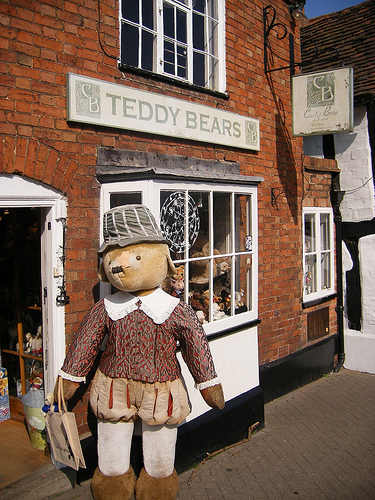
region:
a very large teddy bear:
[44, 191, 233, 492]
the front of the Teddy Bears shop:
[9, 5, 302, 494]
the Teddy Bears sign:
[61, 69, 280, 152]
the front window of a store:
[95, 153, 275, 341]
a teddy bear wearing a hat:
[88, 204, 181, 305]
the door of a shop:
[0, 171, 85, 487]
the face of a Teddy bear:
[106, 254, 141, 288]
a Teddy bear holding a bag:
[29, 193, 184, 474]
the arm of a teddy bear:
[184, 319, 226, 424]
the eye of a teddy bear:
[133, 253, 142, 264]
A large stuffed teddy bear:
[45, 203, 226, 497]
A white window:
[300, 204, 336, 303]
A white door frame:
[1, 169, 65, 448]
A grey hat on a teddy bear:
[98, 202, 172, 251]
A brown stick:
[187, 421, 259, 483]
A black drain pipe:
[328, 171, 346, 372]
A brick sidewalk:
[43, 365, 373, 498]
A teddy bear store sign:
[65, 69, 261, 151]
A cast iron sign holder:
[261, 5, 349, 73]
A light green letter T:
[104, 91, 122, 116]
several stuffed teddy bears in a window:
[156, 210, 274, 336]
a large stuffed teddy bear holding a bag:
[41, 199, 194, 493]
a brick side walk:
[267, 388, 360, 490]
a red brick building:
[69, 151, 318, 370]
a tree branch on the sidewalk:
[173, 414, 269, 494]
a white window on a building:
[288, 191, 336, 316]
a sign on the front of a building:
[49, 73, 284, 136]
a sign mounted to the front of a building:
[252, 6, 344, 138]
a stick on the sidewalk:
[171, 412, 276, 499]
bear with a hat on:
[36, 199, 258, 432]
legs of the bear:
[95, 413, 198, 475]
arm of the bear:
[179, 305, 233, 403]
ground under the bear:
[227, 437, 282, 496]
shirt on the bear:
[73, 308, 202, 386]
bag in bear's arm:
[26, 370, 90, 481]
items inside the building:
[1, 280, 46, 373]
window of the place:
[182, 181, 267, 264]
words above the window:
[79, 89, 287, 149]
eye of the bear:
[131, 246, 152, 269]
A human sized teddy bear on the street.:
[65, 205, 229, 499]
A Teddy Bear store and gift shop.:
[53, 57, 277, 164]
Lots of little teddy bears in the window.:
[178, 247, 266, 327]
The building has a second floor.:
[111, 0, 262, 97]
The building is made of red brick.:
[1, 0, 120, 111]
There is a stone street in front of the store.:
[283, 408, 374, 488]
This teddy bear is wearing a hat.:
[87, 196, 190, 298]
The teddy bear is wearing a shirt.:
[46, 281, 253, 389]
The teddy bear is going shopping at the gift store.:
[21, 361, 94, 477]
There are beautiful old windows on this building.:
[135, 0, 257, 105]